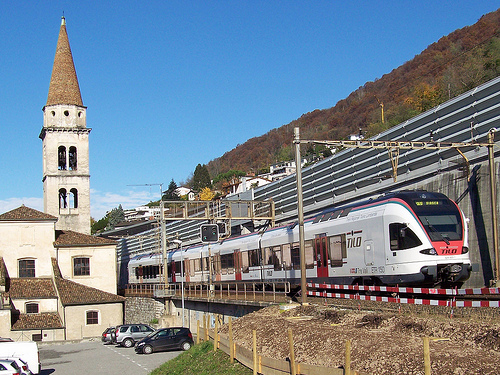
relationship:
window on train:
[322, 232, 350, 272] [303, 180, 473, 291]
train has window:
[117, 188, 474, 288] [217, 254, 237, 269]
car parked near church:
[135, 325, 192, 354] [14, 13, 130, 344]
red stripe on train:
[171, 196, 466, 251] [122, 181, 479, 289]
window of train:
[188, 256, 210, 274] [122, 181, 479, 289]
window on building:
[22, 302, 44, 316] [7, 24, 128, 349]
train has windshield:
[169, 198, 484, 305] [408, 207, 462, 240]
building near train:
[99, 79, 496, 296] [122, 181, 479, 289]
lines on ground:
[101, 113, 490, 263] [39, 337, 139, 373]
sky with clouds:
[0, 1, 500, 222] [90, 185, 158, 201]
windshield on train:
[408, 207, 462, 240] [122, 181, 479, 289]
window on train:
[387, 222, 423, 253] [122, 181, 479, 289]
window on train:
[321, 238, 328, 265] [122, 181, 479, 289]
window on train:
[305, 240, 315, 269] [122, 181, 479, 289]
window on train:
[291, 243, 298, 268] [122, 181, 479, 289]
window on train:
[281, 243, 291, 265] [122, 181, 479, 289]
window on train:
[271, 247, 281, 264] [122, 181, 479, 289]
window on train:
[263, 247, 272, 265] [122, 181, 479, 289]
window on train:
[249, 248, 259, 265] [122, 181, 479, 289]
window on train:
[238, 251, 248, 264] [122, 181, 479, 289]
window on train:
[219, 254, 234, 265] [122, 181, 479, 289]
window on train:
[193, 257, 208, 267] [122, 181, 479, 289]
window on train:
[190, 258, 192, 273] [122, 181, 479, 289]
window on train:
[168, 264, 171, 275] [122, 181, 479, 289]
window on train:
[173, 262, 180, 272] [122, 181, 479, 289]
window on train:
[153, 265, 156, 276] [122, 181, 479, 289]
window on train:
[149, 265, 152, 275] [122, 181, 479, 289]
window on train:
[146, 267, 148, 277] [122, 181, 479, 289]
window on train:
[141, 264, 146, 277] [122, 181, 479, 289]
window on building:
[17, 257, 37, 279] [1, 202, 126, 342]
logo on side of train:
[343, 228, 365, 251] [117, 188, 474, 288]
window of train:
[281, 238, 314, 268] [122, 181, 479, 289]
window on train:
[290, 242, 302, 268] [117, 188, 474, 288]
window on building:
[58, 280, 129, 328] [4, 203, 154, 347]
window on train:
[321, 238, 328, 265] [117, 188, 474, 288]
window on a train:
[372, 222, 428, 256] [126, 195, 454, 275]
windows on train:
[148, 233, 362, 277] [117, 188, 474, 288]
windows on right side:
[148, 233, 362, 277] [128, 214, 386, 286]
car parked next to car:
[112, 323, 154, 347] [135, 325, 192, 354]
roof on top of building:
[9, 199, 56, 225] [3, 200, 60, 279]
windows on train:
[143, 254, 353, 274] [113, 180, 475, 304]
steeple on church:
[41, 15, 87, 109] [0, 5, 127, 350]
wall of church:
[20, 204, 120, 348] [0, 5, 127, 350]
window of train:
[324, 234, 348, 267] [113, 180, 475, 304]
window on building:
[10, 254, 40, 284] [11, 65, 144, 356]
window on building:
[69, 249, 92, 280] [11, 65, 144, 356]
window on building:
[80, 304, 106, 330] [11, 65, 144, 356]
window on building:
[25, 302, 41, 316] [11, 65, 144, 356]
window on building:
[72, 255, 87, 276] [0, 10, 124, 342]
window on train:
[412, 210, 462, 241] [122, 181, 479, 289]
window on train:
[388, 221, 423, 251] [117, 188, 474, 288]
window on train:
[280, 241, 293, 269] [117, 188, 474, 288]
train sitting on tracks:
[117, 188, 474, 288] [125, 277, 497, 309]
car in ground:
[135, 325, 192, 354] [34, 337, 180, 374]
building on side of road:
[1, 8, 141, 361] [116, 127, 485, 310]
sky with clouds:
[2, 2, 495, 219] [2, 185, 164, 222]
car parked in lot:
[135, 325, 192, 354] [2, 332, 188, 373]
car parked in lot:
[112, 323, 154, 347] [2, 332, 188, 373]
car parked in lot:
[100, 327, 115, 344] [2, 332, 188, 373]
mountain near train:
[162, 7, 499, 201] [113, 180, 475, 304]